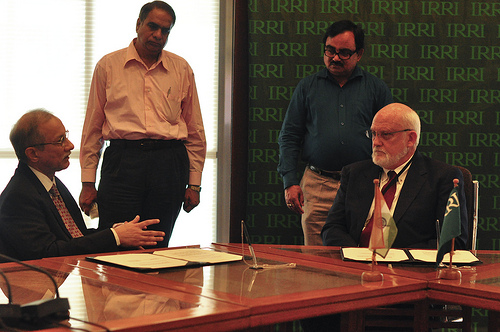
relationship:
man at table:
[0, 101, 175, 264] [4, 241, 479, 330]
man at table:
[321, 102, 472, 245] [4, 241, 479, 330]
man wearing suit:
[0, 101, 175, 264] [0, 159, 123, 260]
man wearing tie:
[0, 101, 175, 264] [50, 186, 84, 238]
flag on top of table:
[360, 177, 400, 285] [4, 241, 479, 330]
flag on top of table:
[435, 186, 461, 269] [4, 241, 479, 330]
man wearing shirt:
[73, 1, 213, 250] [73, 38, 210, 192]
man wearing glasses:
[268, 13, 404, 251] [319, 45, 359, 64]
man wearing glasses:
[321, 102, 472, 245] [363, 124, 413, 145]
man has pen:
[73, 1, 213, 250] [163, 87, 173, 102]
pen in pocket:
[163, 87, 173, 102] [153, 93, 183, 123]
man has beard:
[312, 92, 474, 251] [370, 149, 410, 176]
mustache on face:
[327, 58, 344, 69] [320, 37, 354, 78]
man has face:
[268, 13, 404, 251] [320, 37, 354, 78]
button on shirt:
[334, 99, 344, 112] [274, 58, 390, 193]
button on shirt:
[337, 119, 347, 131] [274, 58, 390, 193]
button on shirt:
[339, 139, 344, 147] [274, 58, 390, 193]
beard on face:
[365, 145, 413, 172] [369, 114, 406, 170]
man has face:
[321, 102, 472, 245] [369, 114, 406, 170]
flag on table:
[369, 177, 400, 259] [4, 241, 479, 330]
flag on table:
[432, 175, 466, 282] [4, 241, 479, 330]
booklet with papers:
[78, 245, 254, 278] [91, 248, 190, 277]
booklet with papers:
[78, 245, 254, 278] [153, 245, 243, 270]